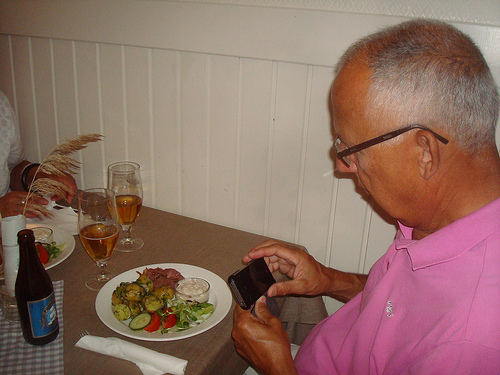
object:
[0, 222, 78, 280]
plate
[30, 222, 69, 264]
food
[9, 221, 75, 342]
bottle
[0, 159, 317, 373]
table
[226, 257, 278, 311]
device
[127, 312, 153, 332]
cucumber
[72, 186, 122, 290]
glasses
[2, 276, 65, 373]
mat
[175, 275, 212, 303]
dressing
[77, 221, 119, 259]
beer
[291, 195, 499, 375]
polo shirt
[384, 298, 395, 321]
logo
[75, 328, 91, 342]
utensils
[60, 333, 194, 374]
rolled napkin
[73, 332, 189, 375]
napkin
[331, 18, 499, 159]
hair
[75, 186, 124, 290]
glass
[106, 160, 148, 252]
glass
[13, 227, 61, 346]
beer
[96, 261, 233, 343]
plate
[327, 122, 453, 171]
glasses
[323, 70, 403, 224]
man's face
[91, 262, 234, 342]
white plate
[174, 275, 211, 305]
glass bowl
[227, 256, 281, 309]
cell phone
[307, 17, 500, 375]
man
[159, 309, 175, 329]
tomato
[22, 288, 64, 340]
blue label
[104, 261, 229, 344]
food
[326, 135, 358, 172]
lenses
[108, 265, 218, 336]
salad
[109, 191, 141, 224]
beer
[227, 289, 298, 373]
hand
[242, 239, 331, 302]
hand